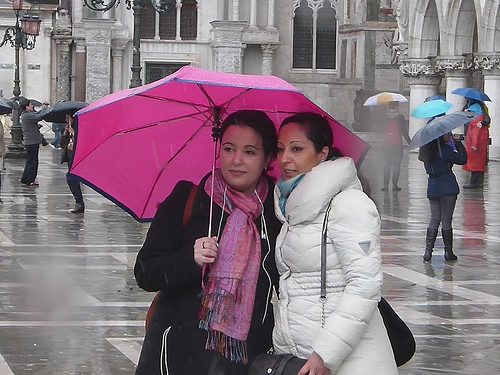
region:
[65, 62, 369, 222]
pink umbrella with purple trim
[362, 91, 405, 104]
white and yellow umbrella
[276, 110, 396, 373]
women in a white fluffy coat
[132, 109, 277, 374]
woman wearing a pink paisley scarf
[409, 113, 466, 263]
woman wearing a blue coat with a gray umbrella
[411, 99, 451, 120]
bright blue umbrella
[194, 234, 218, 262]
hand with a ring on the middle finger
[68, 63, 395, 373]
two women sharing an umbrella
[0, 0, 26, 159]
a decorative streetlamp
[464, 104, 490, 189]
person with a long red coat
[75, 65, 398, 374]
two women standing under an umbrella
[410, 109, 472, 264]
a woman holding an umbrella in the rain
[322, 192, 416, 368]
woman carrying a black purse on her shoulder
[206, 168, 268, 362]
woman wearing a pink scarf around her neck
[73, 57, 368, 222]
a pink umbrella with blue borders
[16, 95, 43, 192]
a man standing in the rain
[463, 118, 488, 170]
a person wearing a red raincoat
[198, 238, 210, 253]
a woman wearing a wedding ring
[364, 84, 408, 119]
a person holding a whit and yellow umbrella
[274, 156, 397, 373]
a woman wearing a white coat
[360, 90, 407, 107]
White and yellow umbrella.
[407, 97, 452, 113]
Light bright blue umbrella.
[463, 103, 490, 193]
Woman wearing red raincoat.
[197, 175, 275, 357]
Light pink scarf with tassels.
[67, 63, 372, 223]
Pink umbrella with purple border.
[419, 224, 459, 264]
Black boots worn by woman by dark blue coats.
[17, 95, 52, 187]
Man taking photo in grey top and black pants.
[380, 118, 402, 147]
Red backpack being worn by a person.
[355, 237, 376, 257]
Grey triangle on white coat.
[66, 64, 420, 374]
Two woman standing under pink umbrella.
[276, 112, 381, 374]
A woman in a puffy white coat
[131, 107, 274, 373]
A woman wearing a black coat and pink scarf.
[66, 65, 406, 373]
Two women standing under a pink umbrella.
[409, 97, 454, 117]
A person holding a light blue umbrella.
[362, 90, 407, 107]
A person holding up a white and gold color umbrella.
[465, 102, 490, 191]
A person wearing a red rain coat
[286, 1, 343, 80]
An fancy double window on the big building.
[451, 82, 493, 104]
A person holding a dark blue umbrella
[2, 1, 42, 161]
A tall black lamppost with three lanterns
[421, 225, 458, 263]
A person wearing a pair of black boots.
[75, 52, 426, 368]
two women standing under same umbrella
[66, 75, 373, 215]
pink umbrella with blue trim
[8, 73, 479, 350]
pedestrians with umbrellas in rain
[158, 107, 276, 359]
woman wearing pink scarf with fringe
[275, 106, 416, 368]
woman wearing puffy white jacket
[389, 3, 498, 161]
ornate cement columns on building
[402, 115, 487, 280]
woman carrying black umbrella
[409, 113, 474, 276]
woman wearing black rain boots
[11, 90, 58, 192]
man taking picture in rain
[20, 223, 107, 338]
rain drops splashing on sidewalk